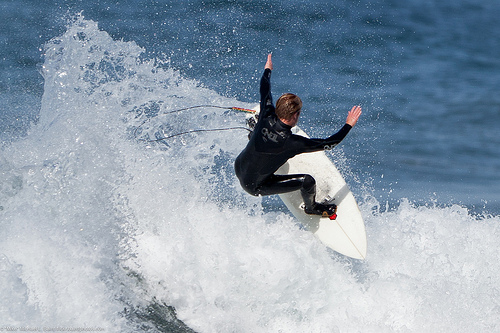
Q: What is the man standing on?
A: Surfboard.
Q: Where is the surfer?
A: In water.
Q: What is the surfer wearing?
A: Wetsuit.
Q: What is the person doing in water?
A: Surfing.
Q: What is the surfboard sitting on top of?
A: Waves.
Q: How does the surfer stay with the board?
A: Using a rope.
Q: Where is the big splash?
A: Behind the man.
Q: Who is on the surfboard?
A: The man.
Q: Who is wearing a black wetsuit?
A: The man.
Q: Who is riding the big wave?
A: The man.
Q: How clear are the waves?
A: Crystal clear.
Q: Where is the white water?
A: Near the man.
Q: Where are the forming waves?
A: Behind the white wave.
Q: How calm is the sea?
A: Not calm at all.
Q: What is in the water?
A: A surfer.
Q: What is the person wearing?
A: A wetsuit.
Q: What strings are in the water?
A: Cables.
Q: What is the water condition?
A: Choppy.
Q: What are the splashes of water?
A: Waves.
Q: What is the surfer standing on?
A: A surfboard.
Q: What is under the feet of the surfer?
A: A board.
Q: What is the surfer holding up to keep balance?
A: His hands.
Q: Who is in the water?
A: A surfer.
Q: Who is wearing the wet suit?
A: The surfer.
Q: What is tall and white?
A: The waves.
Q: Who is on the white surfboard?
A: The surfer.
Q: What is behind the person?
A: Calm water.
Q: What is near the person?
A: Large waves.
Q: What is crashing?
A: White waves.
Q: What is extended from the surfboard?
A: Black cables.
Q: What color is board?
A: White.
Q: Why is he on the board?
A: Surfing.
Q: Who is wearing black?
A: Surfer.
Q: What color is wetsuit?
A: Black.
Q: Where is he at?
A: Ocean.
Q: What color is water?
A: Blue.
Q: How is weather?
A: Sunny.